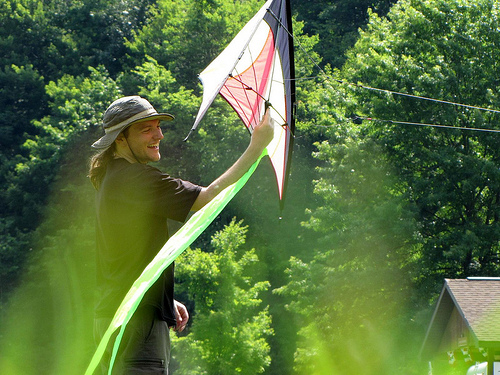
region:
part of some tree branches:
[402, 157, 457, 203]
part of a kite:
[147, 235, 187, 281]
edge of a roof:
[445, 297, 477, 325]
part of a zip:
[148, 355, 168, 370]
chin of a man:
[147, 154, 162, 165]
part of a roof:
[462, 282, 492, 316]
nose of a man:
[151, 127, 168, 142]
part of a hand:
[167, 302, 194, 334]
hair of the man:
[89, 154, 110, 173]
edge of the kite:
[272, 142, 297, 188]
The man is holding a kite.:
[64, 0, 311, 254]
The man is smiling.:
[80, 104, 190, 183]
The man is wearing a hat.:
[74, 90, 182, 155]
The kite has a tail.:
[72, 129, 287, 374]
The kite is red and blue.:
[178, 1, 315, 208]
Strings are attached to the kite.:
[280, 53, 498, 148]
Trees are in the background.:
[275, 1, 497, 286]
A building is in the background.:
[400, 268, 497, 373]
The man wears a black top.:
[84, 157, 218, 326]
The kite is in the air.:
[175, 0, 326, 207]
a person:
[76, 78, 278, 373]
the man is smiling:
[71, 85, 273, 373]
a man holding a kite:
[78, 5, 317, 373]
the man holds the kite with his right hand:
[71, 11, 302, 366]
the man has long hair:
[73, 89, 266, 374]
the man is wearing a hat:
[77, 80, 244, 373]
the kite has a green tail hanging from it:
[68, 7, 303, 372]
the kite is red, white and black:
[170, 2, 315, 197]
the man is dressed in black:
[56, 60, 257, 366]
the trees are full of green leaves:
[28, 4, 496, 362]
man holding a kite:
[90, 93, 277, 373]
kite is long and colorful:
[83, 0, 296, 373]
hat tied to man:
[87, 93, 173, 153]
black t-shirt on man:
[94, 155, 202, 329]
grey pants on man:
[92, 316, 172, 373]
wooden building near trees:
[419, 274, 499, 374]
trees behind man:
[1, 0, 498, 374]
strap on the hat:
[118, 131, 138, 166]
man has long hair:
[84, 122, 131, 187]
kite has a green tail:
[76, 140, 270, 372]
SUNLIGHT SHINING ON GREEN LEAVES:
[109, 8, 194, 91]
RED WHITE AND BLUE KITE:
[168, 10, 323, 178]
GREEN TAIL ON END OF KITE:
[171, 141, 302, 270]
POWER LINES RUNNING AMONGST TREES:
[378, 73, 481, 175]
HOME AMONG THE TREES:
[412, 273, 488, 362]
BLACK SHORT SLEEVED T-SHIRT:
[107, 158, 218, 225]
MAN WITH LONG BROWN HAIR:
[75, 95, 189, 182]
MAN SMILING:
[120, 85, 185, 180]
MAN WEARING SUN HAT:
[88, 79, 173, 171]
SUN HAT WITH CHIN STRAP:
[103, 76, 185, 177]